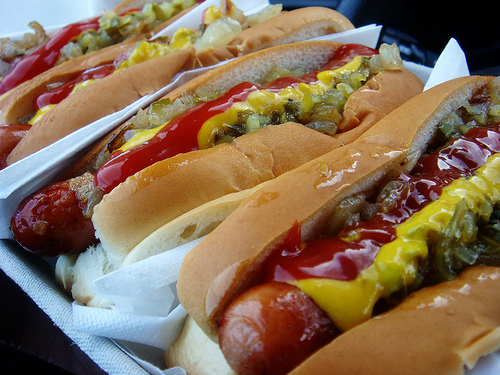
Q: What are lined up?
A: Hot dogs.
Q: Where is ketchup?
A: On hotdog.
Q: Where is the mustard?
A: On hot dog.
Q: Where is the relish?
A: On hotdog.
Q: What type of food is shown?
A: Hotdog.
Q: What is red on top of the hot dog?
A: Ketchup.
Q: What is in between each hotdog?
A: Napkin.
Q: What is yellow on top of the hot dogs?
A: Mustard.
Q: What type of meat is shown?
A: Hot dog.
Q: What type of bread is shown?
A: Bun.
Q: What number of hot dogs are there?
A: 4.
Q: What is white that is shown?
A: Napkin.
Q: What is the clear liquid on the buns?
A: Vinegar.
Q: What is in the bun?
A: Sausage.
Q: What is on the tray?
A: Hot dogs.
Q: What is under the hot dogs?
A: Napkins.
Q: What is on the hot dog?
A: Ketchup and Mustard.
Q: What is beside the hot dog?
A: Napkin.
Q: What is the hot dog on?
A: Food Tray.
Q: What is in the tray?
A: A snack.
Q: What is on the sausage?
A: Bread and relish.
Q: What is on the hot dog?
A: Toppings.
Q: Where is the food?
A: In a restaurant.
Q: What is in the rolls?
A: Hot Dogs.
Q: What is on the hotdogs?
A: Condiments.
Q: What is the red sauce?
A: Ketchup.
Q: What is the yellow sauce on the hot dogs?
A: Mustard.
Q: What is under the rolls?
A: Napkins.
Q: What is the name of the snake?
A: Hot Dogs.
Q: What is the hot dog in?
A: Rolls.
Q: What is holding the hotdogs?
A: Hotdog rolls.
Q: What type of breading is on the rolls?
A: White bread.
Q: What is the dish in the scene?
A: Hot dogs.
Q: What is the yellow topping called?
A: Mustard.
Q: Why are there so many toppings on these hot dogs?
A: For flavor.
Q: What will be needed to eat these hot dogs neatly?
A: Napkins.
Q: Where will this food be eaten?
A: At a table.